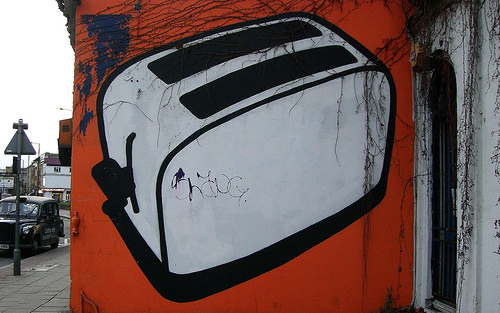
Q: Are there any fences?
A: No, there are no fences.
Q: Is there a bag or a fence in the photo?
A: No, there are no fences or bags.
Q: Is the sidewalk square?
A: Yes, the sidewalk is square.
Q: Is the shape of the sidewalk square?
A: Yes, the sidewalk is square.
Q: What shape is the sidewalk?
A: The sidewalk is square.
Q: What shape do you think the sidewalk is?
A: The sidewalk is square.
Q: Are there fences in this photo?
A: No, there are no fences.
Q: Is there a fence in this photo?
A: No, there are no fences.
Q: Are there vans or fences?
A: No, there are no fences or vans.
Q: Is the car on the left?
A: Yes, the car is on the left of the image.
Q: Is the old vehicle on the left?
A: Yes, the car is on the left of the image.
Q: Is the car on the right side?
A: No, the car is on the left of the image.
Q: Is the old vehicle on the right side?
A: No, the car is on the left of the image.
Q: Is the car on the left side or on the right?
A: The car is on the left of the image.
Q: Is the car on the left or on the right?
A: The car is on the left of the image.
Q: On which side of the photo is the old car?
A: The car is on the left of the image.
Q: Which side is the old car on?
A: The car is on the left of the image.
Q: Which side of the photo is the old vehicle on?
A: The car is on the left of the image.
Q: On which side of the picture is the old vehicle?
A: The car is on the left of the image.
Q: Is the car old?
A: Yes, the car is old.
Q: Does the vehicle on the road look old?
A: Yes, the car is old.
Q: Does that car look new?
A: No, the car is old.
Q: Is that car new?
A: No, the car is old.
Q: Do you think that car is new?
A: No, the car is old.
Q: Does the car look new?
A: No, the car is old.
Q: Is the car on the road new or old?
A: The car is old.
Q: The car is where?
A: The car is on the road.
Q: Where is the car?
A: The car is on the road.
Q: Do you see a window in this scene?
A: Yes, there is a window.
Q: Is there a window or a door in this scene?
A: Yes, there is a window.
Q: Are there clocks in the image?
A: No, there are no clocks.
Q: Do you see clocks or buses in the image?
A: No, there are no clocks or buses.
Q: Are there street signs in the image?
A: Yes, there is a street sign.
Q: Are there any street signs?
A: Yes, there is a street sign.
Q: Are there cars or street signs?
A: Yes, there is a street sign.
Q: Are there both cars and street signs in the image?
A: Yes, there are both a street sign and a car.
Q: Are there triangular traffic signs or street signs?
A: Yes, there is a triangular street sign.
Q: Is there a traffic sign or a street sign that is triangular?
A: Yes, the street sign is triangular.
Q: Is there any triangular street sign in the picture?
A: Yes, there is a triangular street sign.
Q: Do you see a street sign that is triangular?
A: Yes, there is a street sign that is triangular.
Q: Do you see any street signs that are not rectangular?
A: Yes, there is a triangular street sign.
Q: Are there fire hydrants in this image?
A: No, there are no fire hydrants.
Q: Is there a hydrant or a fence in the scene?
A: No, there are no fire hydrants or fences.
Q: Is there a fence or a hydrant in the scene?
A: No, there are no fire hydrants or fences.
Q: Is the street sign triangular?
A: Yes, the street sign is triangular.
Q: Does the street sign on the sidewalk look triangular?
A: Yes, the street sign is triangular.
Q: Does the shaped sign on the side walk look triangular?
A: Yes, the street sign is triangular.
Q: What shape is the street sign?
A: The street sign is triangular.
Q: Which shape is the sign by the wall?
A: The street sign is triangular.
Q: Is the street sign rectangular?
A: No, the street sign is triangular.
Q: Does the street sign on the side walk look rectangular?
A: No, the street sign is triangular.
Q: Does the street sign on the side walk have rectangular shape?
A: No, the street sign is triangular.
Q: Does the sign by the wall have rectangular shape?
A: No, the street sign is triangular.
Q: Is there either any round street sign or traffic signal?
A: No, there is a street sign but it is triangular.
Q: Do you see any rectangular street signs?
A: No, there is a street sign but it is triangular.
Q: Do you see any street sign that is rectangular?
A: No, there is a street sign but it is triangular.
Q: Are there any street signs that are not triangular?
A: No, there is a street sign but it is triangular.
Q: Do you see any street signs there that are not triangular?
A: No, there is a street sign but it is triangular.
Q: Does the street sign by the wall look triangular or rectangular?
A: The street sign is triangular.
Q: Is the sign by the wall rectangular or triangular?
A: The street sign is triangular.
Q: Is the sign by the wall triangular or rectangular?
A: The street sign is triangular.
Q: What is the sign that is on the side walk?
A: The sign is a street sign.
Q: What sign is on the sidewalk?
A: The sign is a street sign.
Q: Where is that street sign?
A: The street sign is on the side walk.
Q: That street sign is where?
A: The street sign is on the side walk.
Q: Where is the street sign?
A: The street sign is on the side walk.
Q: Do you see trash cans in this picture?
A: No, there are no trash cans.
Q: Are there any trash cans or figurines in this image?
A: No, there are no trash cans or figurines.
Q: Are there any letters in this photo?
A: Yes, there are letters.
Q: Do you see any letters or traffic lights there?
A: Yes, there are letters.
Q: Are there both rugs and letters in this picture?
A: No, there are letters but no rugs.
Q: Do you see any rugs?
A: No, there are no rugs.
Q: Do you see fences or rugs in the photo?
A: No, there are no rugs or fences.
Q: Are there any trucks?
A: No, there are no trucks.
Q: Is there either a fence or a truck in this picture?
A: No, there are no trucks or fences.